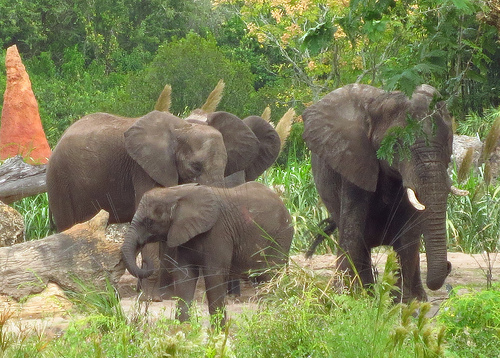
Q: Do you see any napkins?
A: No, there are no napkins.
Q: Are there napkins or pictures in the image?
A: No, there are no napkins or pictures.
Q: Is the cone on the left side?
A: Yes, the cone is on the left of the image.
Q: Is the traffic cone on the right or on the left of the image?
A: The traffic cone is on the left of the image.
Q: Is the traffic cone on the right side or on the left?
A: The traffic cone is on the left of the image.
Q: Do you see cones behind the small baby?
A: Yes, there is a cone behind the baby.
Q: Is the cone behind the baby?
A: Yes, the cone is behind the baby.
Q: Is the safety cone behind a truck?
A: No, the safety cone is behind the baby.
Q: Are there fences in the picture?
A: No, there are no fences.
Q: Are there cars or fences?
A: No, there are no fences or cars.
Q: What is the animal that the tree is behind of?
A: The animal is an elephant.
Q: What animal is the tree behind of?
A: The tree is behind the elephant.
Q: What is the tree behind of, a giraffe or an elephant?
A: The tree is behind an elephant.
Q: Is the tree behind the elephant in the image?
A: Yes, the tree is behind the elephant.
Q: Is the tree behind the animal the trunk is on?
A: Yes, the tree is behind the elephant.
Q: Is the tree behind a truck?
A: No, the tree is behind the elephant.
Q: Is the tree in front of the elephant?
A: No, the tree is behind the elephant.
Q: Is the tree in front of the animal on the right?
A: No, the tree is behind the elephant.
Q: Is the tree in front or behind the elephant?
A: The tree is behind the elephant.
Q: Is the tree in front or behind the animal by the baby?
A: The tree is behind the elephant.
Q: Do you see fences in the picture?
A: No, there are no fences.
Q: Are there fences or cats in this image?
A: No, there are no fences or cats.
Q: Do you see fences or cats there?
A: No, there are no fences or cats.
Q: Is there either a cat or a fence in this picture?
A: No, there are no fences or cats.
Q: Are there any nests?
A: No, there are no nests.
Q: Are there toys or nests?
A: No, there are no nests or toys.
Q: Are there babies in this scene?
A: Yes, there is a baby.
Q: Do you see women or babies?
A: Yes, there is a baby.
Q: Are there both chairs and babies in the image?
A: No, there is a baby but no chairs.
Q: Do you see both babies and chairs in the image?
A: No, there is a baby but no chairs.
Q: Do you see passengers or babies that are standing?
A: Yes, the baby is standing.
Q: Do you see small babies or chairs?
A: Yes, there is a small baby.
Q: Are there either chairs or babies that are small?
A: Yes, the baby is small.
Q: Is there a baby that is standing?
A: Yes, there is a baby that is standing.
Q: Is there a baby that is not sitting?
A: Yes, there is a baby that is standing.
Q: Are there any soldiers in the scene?
A: No, there are no soldiers.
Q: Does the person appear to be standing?
A: Yes, the baby is standing.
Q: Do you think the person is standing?
A: Yes, the baby is standing.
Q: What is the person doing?
A: The baby is standing.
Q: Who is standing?
A: The baby is standing.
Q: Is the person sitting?
A: No, the baby is standing.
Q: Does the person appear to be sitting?
A: No, the baby is standing.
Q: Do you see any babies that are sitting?
A: No, there is a baby but he is standing.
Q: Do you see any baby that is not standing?
A: No, there is a baby but he is standing.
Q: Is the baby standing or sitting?
A: The baby is standing.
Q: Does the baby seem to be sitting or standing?
A: The baby is standing.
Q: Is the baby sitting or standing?
A: The baby is standing.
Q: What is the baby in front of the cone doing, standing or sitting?
A: The baby is standing.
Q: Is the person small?
A: Yes, the baby is small.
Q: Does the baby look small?
A: Yes, the baby is small.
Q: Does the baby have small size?
A: Yes, the baby is small.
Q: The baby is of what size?
A: The baby is small.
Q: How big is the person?
A: The baby is small.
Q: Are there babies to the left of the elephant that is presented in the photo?
A: Yes, there is a baby to the left of the elephant.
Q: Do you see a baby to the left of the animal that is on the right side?
A: Yes, there is a baby to the left of the elephant.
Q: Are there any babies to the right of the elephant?
A: No, the baby is to the left of the elephant.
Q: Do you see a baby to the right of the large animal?
A: No, the baby is to the left of the elephant.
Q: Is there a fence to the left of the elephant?
A: No, there is a baby to the left of the elephant.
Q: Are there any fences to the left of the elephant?
A: No, there is a baby to the left of the elephant.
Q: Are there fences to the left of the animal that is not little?
A: No, there is a baby to the left of the elephant.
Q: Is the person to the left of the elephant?
A: Yes, the baby is to the left of the elephant.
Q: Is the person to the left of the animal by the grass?
A: Yes, the baby is to the left of the elephant.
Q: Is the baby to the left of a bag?
A: No, the baby is to the left of the elephant.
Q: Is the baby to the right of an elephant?
A: No, the baby is to the left of an elephant.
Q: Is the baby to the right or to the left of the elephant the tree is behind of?
A: The baby is to the left of the elephant.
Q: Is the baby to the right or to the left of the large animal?
A: The baby is to the left of the elephant.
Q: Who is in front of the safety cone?
A: The baby is in front of the safety cone.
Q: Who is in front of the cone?
A: The baby is in front of the safety cone.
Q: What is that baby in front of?
A: The baby is in front of the safety cone.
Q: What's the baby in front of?
A: The baby is in front of the safety cone.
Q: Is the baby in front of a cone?
A: Yes, the baby is in front of a cone.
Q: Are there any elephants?
A: Yes, there is an elephant.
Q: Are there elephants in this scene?
A: Yes, there is an elephant.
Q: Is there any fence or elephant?
A: Yes, there is an elephant.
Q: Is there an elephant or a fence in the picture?
A: Yes, there is an elephant.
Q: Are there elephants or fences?
A: Yes, there is an elephant.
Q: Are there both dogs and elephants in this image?
A: No, there is an elephant but no dogs.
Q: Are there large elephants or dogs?
A: Yes, there is a large elephant.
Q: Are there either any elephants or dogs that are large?
A: Yes, the elephant is large.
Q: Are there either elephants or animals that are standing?
A: Yes, the elephant is standing.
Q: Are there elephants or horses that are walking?
A: Yes, the elephant is walking.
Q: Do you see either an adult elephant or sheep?
A: Yes, there is an adult elephant.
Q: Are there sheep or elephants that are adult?
A: Yes, the elephant is adult.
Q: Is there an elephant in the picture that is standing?
A: Yes, there is an elephant that is standing.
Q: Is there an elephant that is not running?
A: Yes, there is an elephant that is standing.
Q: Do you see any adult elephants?
A: Yes, there is an adult elephant.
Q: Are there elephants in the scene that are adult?
A: Yes, there is an elephant that is adult.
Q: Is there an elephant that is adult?
A: Yes, there is an elephant that is adult.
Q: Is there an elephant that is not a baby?
A: Yes, there is a adult elephant.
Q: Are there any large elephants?
A: Yes, there is a large elephant.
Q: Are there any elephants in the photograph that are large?
A: Yes, there is an elephant that is large.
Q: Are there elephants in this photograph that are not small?
A: Yes, there is a large elephant.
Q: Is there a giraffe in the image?
A: No, there are no giraffes.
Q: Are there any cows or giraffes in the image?
A: No, there are no giraffes or cows.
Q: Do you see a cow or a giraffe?
A: No, there are no giraffes or cows.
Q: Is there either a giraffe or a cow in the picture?
A: No, there are no giraffes or cows.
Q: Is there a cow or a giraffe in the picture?
A: No, there are no giraffes or cows.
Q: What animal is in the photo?
A: The animal is an elephant.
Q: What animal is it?
A: The animal is an elephant.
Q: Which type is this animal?
A: This is an elephant.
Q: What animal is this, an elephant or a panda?
A: This is an elephant.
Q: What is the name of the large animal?
A: The animal is an elephant.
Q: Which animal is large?
A: The animal is an elephant.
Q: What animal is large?
A: The animal is an elephant.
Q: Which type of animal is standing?
A: The animal is an elephant.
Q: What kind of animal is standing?
A: The animal is an elephant.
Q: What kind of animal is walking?
A: The animal is an elephant.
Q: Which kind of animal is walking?
A: The animal is an elephant.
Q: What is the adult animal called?
A: The animal is an elephant.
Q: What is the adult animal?
A: The animal is an elephant.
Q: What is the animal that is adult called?
A: The animal is an elephant.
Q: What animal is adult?
A: The animal is an elephant.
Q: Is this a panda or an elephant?
A: This is an elephant.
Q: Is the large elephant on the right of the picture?
A: Yes, the elephant is on the right of the image.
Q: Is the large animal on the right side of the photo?
A: Yes, the elephant is on the right of the image.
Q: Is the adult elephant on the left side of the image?
A: No, the elephant is on the right of the image.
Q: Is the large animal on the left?
A: No, the elephant is on the right of the image.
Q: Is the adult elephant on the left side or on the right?
A: The elephant is on the right of the image.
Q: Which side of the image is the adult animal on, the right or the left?
A: The elephant is on the right of the image.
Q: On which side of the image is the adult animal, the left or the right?
A: The elephant is on the right of the image.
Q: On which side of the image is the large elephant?
A: The elephant is on the right of the image.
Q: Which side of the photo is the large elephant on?
A: The elephant is on the right of the image.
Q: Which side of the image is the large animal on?
A: The elephant is on the right of the image.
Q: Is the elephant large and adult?
A: Yes, the elephant is large and adult.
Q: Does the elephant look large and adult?
A: Yes, the elephant is large and adult.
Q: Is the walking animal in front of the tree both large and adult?
A: Yes, the elephant is large and adult.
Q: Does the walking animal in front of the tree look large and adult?
A: Yes, the elephant is large and adult.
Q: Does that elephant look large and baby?
A: No, the elephant is large but adult.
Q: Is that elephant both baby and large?
A: No, the elephant is large but adult.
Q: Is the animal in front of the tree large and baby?
A: No, the elephant is large but adult.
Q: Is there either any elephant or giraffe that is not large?
A: No, there is an elephant but it is large.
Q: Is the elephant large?
A: Yes, the elephant is large.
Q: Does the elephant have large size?
A: Yes, the elephant is large.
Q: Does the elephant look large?
A: Yes, the elephant is large.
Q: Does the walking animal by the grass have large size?
A: Yes, the elephant is large.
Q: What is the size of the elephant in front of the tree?
A: The elephant is large.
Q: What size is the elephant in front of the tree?
A: The elephant is large.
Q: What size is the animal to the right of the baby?
A: The elephant is large.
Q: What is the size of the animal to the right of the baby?
A: The elephant is large.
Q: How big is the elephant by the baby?
A: The elephant is large.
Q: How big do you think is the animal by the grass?
A: The elephant is large.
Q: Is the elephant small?
A: No, the elephant is large.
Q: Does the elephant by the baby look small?
A: No, the elephant is large.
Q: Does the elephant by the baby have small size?
A: No, the elephant is large.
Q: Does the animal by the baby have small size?
A: No, the elephant is large.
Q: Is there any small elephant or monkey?
A: No, there is an elephant but it is large.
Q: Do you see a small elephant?
A: No, there is an elephant but it is large.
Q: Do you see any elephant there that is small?
A: No, there is an elephant but it is large.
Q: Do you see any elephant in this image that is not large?
A: No, there is an elephant but it is large.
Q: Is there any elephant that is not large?
A: No, there is an elephant but it is large.